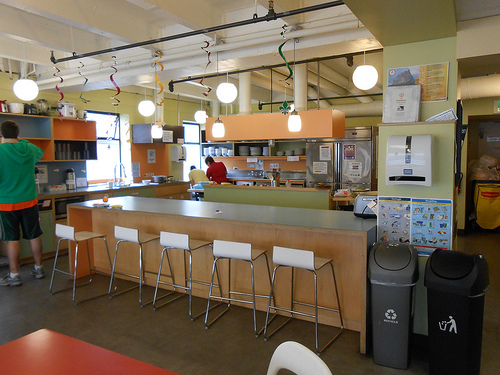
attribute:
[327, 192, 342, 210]
stand — parted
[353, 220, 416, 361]
bin — gray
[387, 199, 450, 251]
chart — parted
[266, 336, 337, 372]
chair — white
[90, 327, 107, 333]
floor — parted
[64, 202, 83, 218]
edge — parted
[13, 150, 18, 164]
jacket — green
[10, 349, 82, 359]
table — red, square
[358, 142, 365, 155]
refrigerator — silver, commercial, paired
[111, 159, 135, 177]
faucet — silver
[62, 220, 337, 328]
chairs — white, 6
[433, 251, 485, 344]
garbage can — black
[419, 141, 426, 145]
towel holder — white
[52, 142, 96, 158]
bottles — assorted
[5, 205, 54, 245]
shorts — dark, black